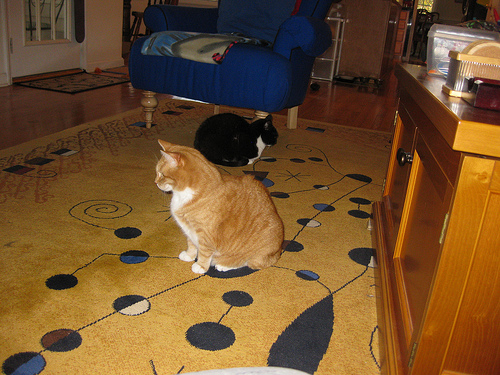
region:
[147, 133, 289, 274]
Orange and white cat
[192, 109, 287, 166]
black and white cat laying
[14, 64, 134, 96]
Mat for wipeing your feet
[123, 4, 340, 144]
blue chair with wooden legs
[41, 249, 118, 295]
circle and line design on carpet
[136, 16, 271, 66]
Blue, tan and red blanket on chair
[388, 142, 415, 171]
Two nobs on cabinet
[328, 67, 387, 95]
Feed and water bowls for cats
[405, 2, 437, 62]
Two dining room chairs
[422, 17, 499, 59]
Clear plastic container with lid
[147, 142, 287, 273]
a brown and white cat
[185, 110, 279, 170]
a black and white cat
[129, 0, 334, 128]
a deep blue chair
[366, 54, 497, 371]
a wooden furniture piece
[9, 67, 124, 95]
a colorful floor mat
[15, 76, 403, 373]
a patterned area rug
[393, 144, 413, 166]
drawer cabinet pulls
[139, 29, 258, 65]
a folded printed blanket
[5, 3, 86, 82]
a closed white door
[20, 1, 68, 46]
three panes of glass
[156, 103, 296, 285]
two cats facing opposite directions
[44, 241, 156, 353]
round designs on rug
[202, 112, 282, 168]
black and white cat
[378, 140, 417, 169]
knobs on wood furniture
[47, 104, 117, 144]
rug on wood floor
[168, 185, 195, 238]
white fur on chest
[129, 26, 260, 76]
blanket on blue chair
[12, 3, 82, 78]
window panels on door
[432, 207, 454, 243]
hinge on wood door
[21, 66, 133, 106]
door mat on floor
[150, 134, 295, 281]
A yellow and white cat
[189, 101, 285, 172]
A black and white cat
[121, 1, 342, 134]
A large blue chair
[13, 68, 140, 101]
A welcome mat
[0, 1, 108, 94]
The bottom half of a door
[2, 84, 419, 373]
A large area rug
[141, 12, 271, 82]
A blanket on a chair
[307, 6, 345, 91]
A white storage bin.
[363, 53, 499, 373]
A wooden storage table.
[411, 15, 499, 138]
Items on a table.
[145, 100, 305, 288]
Two cats are sitting on the floor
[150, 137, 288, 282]
This cat is orange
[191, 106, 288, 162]
This cat is black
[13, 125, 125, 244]
A rug is covering the floor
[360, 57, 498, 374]
This is a wooden cabinet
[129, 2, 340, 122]
This is a blue chair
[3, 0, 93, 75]
This is a door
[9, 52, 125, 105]
A floor mat is in front of the door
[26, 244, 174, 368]
Designs are on the rug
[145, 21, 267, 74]
A blanket is folded on the chair